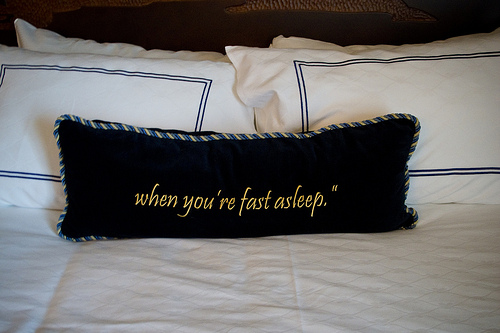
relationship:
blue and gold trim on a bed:
[53, 112, 422, 243] [2, 0, 500, 333]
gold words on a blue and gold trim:
[132, 180, 340, 223] [53, 112, 422, 243]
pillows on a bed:
[1, 17, 499, 211] [2, 0, 500, 333]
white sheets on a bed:
[0, 204, 499, 332] [2, 0, 500, 333]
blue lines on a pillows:
[0, 64, 213, 191] [1, 17, 499, 211]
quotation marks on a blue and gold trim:
[328, 180, 339, 194] [53, 112, 422, 243]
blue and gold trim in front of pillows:
[53, 112, 422, 243] [1, 17, 499, 211]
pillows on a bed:
[1, 17, 499, 244] [2, 0, 500, 333]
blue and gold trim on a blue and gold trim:
[54, 112, 423, 243] [53, 112, 422, 243]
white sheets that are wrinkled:
[0, 204, 499, 332] [162, 257, 296, 316]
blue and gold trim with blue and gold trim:
[53, 112, 422, 243] [54, 112, 423, 243]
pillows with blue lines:
[1, 17, 499, 211] [0, 64, 213, 191]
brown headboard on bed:
[0, 0, 499, 57] [2, 0, 500, 333]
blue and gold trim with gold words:
[53, 112, 422, 243] [132, 180, 340, 223]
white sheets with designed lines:
[0, 204, 499, 332] [279, 235, 305, 331]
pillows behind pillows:
[1, 17, 499, 211] [1, 17, 499, 211]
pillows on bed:
[1, 17, 499, 211] [2, 0, 500, 333]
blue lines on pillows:
[0, 64, 213, 191] [1, 17, 499, 244]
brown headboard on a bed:
[0, 0, 499, 57] [2, 0, 500, 333]